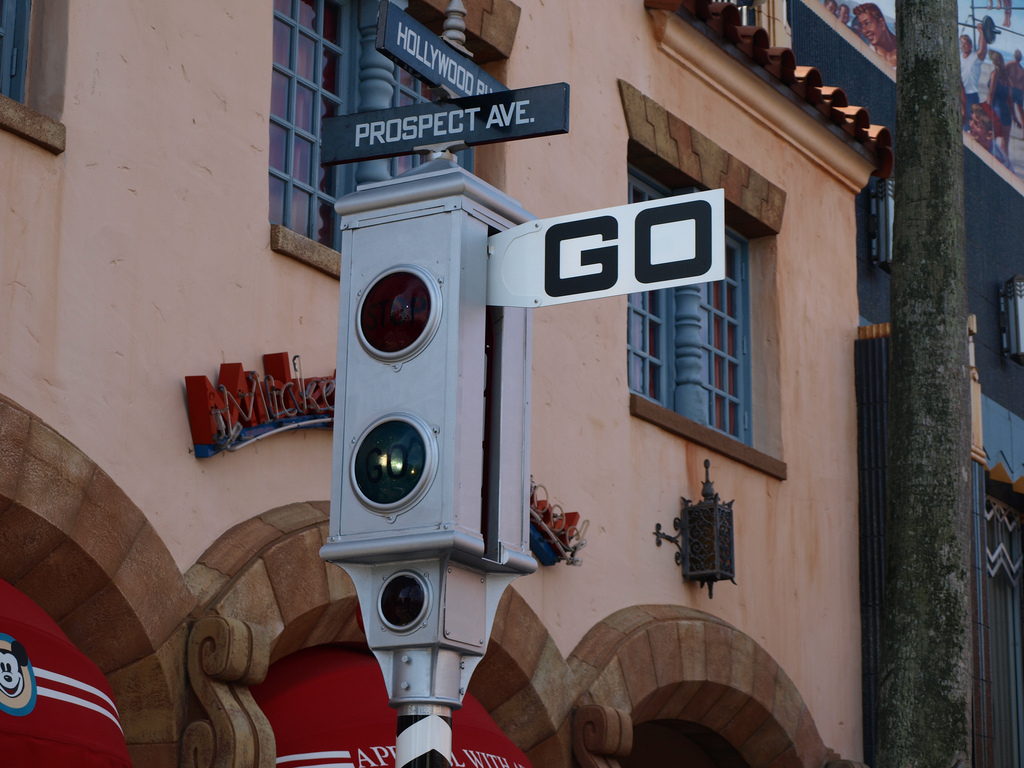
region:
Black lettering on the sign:
[524, 191, 706, 294]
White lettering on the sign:
[349, 92, 543, 154]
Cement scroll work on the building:
[164, 594, 276, 763]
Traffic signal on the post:
[292, 148, 568, 758]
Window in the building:
[597, 86, 788, 491]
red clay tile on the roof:
[691, 0, 910, 168]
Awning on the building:
[239, 621, 546, 764]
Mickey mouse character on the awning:
[3, 624, 49, 727]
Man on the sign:
[852, 0, 906, 73]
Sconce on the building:
[640, 442, 758, 614]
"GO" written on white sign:
[516, 171, 732, 312]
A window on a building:
[604, 128, 769, 468]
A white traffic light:
[288, 140, 538, 761]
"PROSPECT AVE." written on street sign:
[311, 71, 581, 170]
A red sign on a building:
[166, 326, 596, 583]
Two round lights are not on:
[333, 238, 457, 532]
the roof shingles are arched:
[675, 5, 890, 168]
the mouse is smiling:
[5, 628, 28, 701]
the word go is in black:
[544, 213, 721, 297]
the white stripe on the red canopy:
[33, 669, 123, 740]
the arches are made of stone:
[579, 600, 837, 766]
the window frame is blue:
[637, 178, 756, 444]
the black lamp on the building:
[652, 457, 736, 604]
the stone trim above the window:
[614, 81, 786, 234]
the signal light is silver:
[316, 169, 539, 711]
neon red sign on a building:
[164, 334, 595, 572]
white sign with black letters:
[484, 179, 747, 312]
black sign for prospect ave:
[313, 79, 579, 163]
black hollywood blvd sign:
[375, 12, 519, 115]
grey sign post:
[322, 165, 563, 766]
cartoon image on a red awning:
[2, 639, 29, 703]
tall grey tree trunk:
[882, 9, 987, 766]